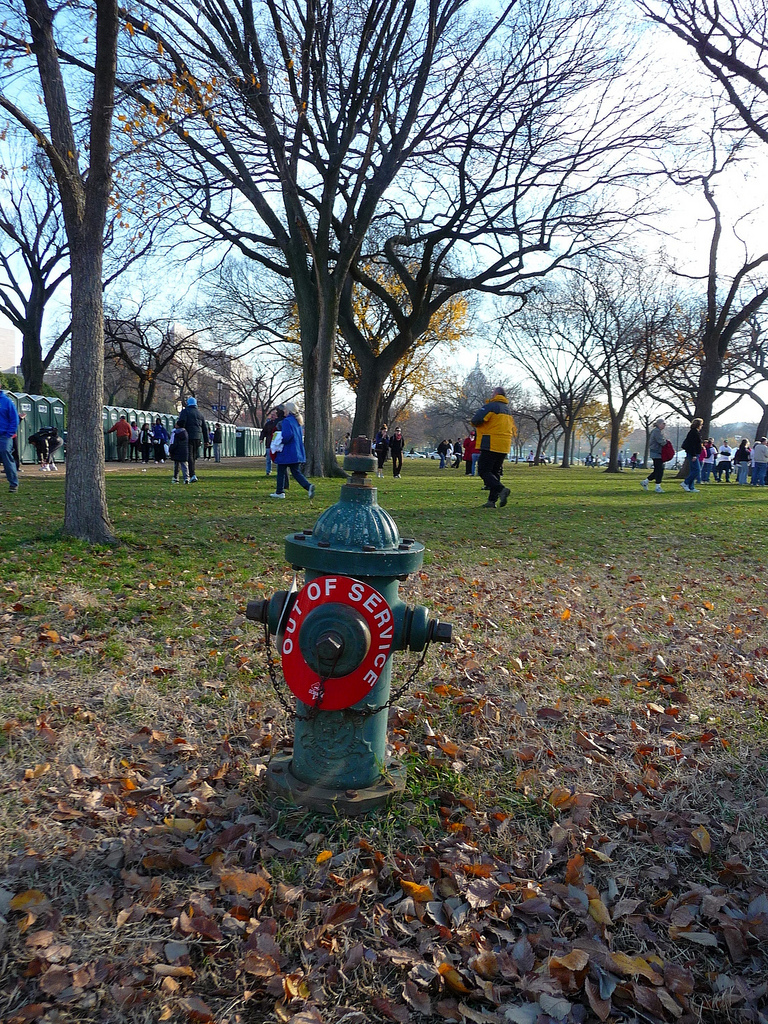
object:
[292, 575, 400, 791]
post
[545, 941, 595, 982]
leaves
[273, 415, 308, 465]
coat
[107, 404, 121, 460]
toilets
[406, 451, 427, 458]
cars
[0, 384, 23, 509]
people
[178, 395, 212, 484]
adult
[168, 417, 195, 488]
child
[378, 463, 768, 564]
grass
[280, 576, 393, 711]
sign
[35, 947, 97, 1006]
leaves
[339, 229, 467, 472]
tree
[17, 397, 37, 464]
portapotties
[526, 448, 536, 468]
people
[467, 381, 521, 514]
man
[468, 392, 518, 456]
jacket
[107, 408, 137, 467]
people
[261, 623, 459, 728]
chain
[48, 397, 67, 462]
portapotty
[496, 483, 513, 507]
shoe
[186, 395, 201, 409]
hat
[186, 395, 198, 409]
head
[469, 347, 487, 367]
steeple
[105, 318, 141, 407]
building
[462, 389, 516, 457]
yellow jacket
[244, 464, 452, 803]
fire hydrant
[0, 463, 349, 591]
grass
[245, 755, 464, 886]
grass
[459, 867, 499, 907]
leaves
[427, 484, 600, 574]
grass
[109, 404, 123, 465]
port-a-potties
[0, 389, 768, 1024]
park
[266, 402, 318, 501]
woman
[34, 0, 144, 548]
tree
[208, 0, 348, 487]
tree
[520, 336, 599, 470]
tree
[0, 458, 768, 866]
grass field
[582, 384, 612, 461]
tree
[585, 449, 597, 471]
people